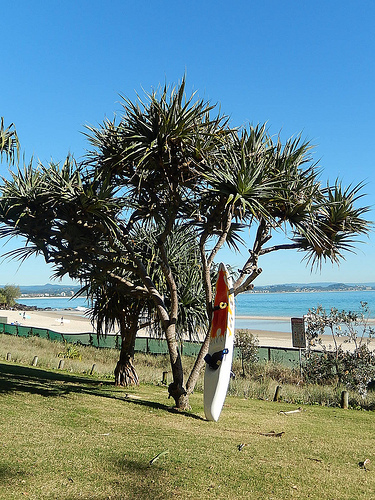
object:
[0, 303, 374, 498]
ground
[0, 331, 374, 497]
field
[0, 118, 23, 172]
leaves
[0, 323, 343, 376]
fence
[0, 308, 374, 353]
beach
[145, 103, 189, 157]
leaves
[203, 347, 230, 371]
seat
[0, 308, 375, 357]
sand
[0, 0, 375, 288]
sky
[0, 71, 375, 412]
tree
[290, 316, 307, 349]
sign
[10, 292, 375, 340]
water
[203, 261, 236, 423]
kayak